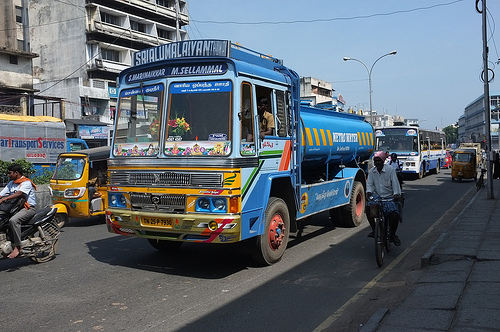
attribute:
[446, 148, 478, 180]
cab — yellow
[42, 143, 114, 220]
vehicle — yellow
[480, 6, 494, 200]
pole — tall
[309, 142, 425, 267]
shirt — white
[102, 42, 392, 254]
truck — blue, yellow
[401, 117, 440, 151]
truck — blue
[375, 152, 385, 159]
turban — orange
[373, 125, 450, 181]
bus — blue, white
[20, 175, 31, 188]
scarf — orange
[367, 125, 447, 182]
bus — blue, white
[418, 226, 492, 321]
pavement — square